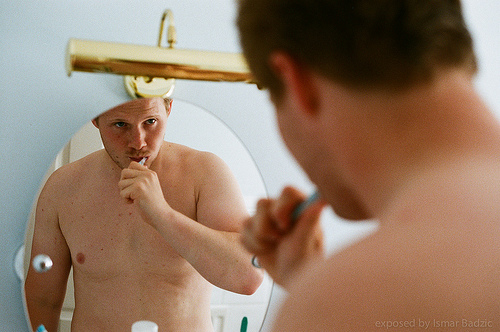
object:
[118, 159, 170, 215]
hand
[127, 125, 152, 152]
man's nose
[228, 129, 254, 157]
edge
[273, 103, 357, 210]
cheek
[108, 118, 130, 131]
eye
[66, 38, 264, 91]
light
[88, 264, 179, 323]
stomach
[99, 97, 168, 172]
face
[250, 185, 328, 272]
toothbrush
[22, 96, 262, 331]
man reflection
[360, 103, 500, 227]
neck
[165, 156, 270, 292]
arm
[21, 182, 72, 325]
arm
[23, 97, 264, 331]
image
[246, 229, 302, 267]
palm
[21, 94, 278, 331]
mirror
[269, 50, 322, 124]
ear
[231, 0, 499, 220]
man's head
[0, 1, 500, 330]
wall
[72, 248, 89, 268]
nipple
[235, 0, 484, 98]
hair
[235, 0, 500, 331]
man looking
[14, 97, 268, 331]
man's reflection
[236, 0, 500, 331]
guy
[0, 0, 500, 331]
bathroom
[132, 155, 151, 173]
toothbrush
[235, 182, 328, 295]
hand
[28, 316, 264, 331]
objects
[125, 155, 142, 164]
teeth